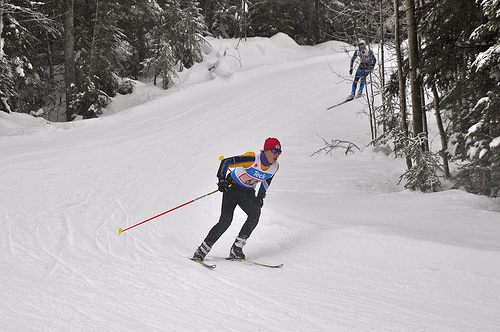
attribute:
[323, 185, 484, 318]
snow — white 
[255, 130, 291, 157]
cap — red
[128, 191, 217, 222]
ski pole — Orange, white 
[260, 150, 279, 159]
goggles — blue